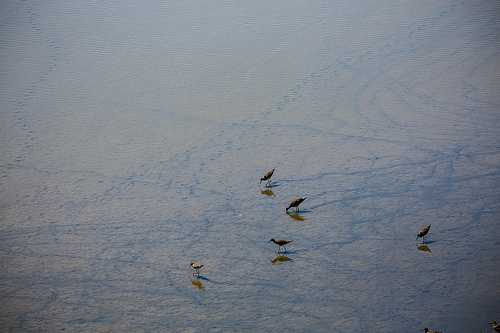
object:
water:
[0, 0, 499, 333]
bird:
[284, 194, 319, 216]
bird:
[268, 238, 294, 252]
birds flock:
[187, 168, 432, 277]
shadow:
[258, 181, 279, 196]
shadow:
[285, 209, 310, 223]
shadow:
[415, 242, 433, 253]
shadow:
[268, 252, 294, 264]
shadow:
[189, 272, 210, 291]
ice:
[0, 0, 499, 333]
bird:
[188, 262, 204, 272]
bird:
[414, 224, 432, 241]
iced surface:
[0, 0, 499, 333]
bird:
[259, 168, 276, 186]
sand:
[0, 233, 500, 332]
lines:
[29, 243, 188, 306]